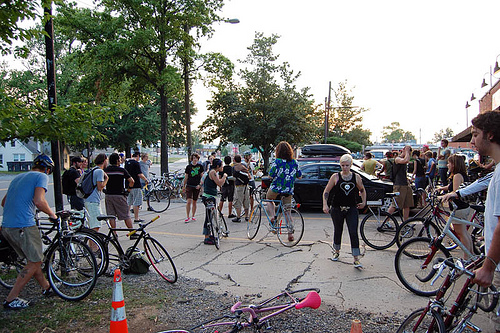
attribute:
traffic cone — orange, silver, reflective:
[109, 268, 131, 331]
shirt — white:
[469, 160, 497, 267]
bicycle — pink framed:
[154, 285, 324, 332]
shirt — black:
[104, 161, 130, 190]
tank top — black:
[329, 174, 361, 209]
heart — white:
[339, 180, 356, 197]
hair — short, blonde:
[324, 135, 355, 170]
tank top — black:
[331, 170, 358, 208]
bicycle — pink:
[175, 278, 357, 332]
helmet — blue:
[22, 150, 57, 177]